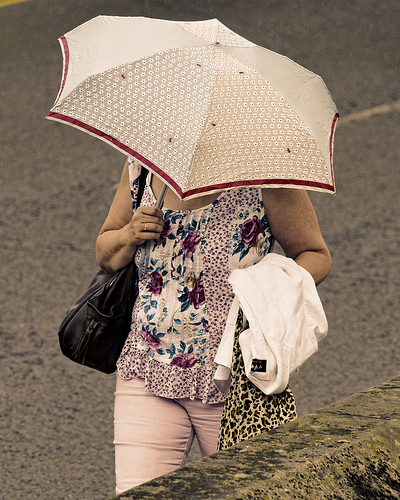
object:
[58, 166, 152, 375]
purse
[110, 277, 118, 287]
zippers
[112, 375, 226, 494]
pants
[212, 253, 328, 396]
clothing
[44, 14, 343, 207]
open umbrella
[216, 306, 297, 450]
material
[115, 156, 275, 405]
blouse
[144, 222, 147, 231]
ring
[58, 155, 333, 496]
lady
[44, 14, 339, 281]
umbrella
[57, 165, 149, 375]
bag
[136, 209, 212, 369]
flowers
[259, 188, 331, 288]
arm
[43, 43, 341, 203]
line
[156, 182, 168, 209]
pole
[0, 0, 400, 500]
rain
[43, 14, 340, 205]
design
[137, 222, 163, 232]
finger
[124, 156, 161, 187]
shoulder